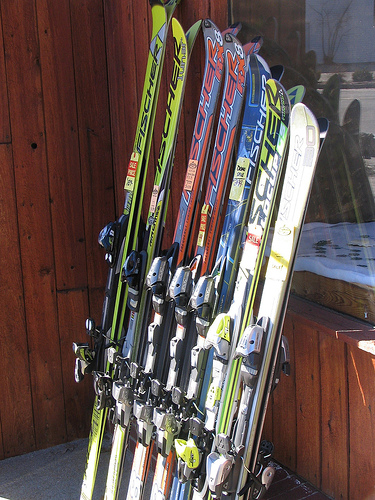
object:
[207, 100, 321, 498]
ski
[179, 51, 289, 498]
ski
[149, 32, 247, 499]
ski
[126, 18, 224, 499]
ski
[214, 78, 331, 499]
ski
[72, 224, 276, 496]
bindings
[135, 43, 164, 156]
writing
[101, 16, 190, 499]
ski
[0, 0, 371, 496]
store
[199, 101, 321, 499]
merchandise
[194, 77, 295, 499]
merchandise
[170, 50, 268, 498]
merchandise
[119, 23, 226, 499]
merchandise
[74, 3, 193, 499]
merchandise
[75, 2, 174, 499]
merchandise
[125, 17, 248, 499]
red skis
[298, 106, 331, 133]
ground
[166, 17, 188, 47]
yellow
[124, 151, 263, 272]
tags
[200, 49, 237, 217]
fischer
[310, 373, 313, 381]
spot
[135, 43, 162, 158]
fischer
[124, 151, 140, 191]
tag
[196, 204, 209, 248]
tag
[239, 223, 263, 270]
tag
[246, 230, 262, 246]
stripe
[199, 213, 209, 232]
stripe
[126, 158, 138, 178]
stripe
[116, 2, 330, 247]
tail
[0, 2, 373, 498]
building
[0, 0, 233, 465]
wall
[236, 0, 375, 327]
window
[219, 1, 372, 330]
store window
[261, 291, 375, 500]
wood paneling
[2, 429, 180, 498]
dusting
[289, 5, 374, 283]
exterior view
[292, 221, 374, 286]
walk area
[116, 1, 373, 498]
store front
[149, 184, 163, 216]
tag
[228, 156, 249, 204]
tag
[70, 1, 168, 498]
ski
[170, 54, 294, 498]
ski